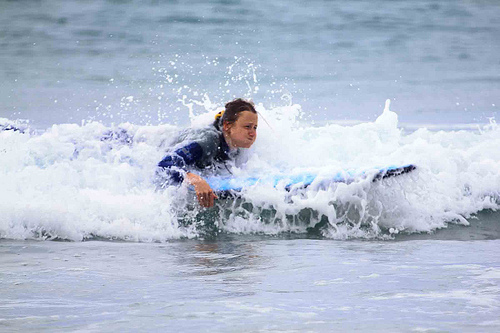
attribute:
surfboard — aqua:
[183, 162, 414, 199]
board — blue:
[161, 157, 424, 201]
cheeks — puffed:
[228, 122, 256, 147]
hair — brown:
[213, 98, 257, 125]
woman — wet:
[87, 88, 258, 218]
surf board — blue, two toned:
[188, 162, 418, 200]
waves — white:
[13, 112, 498, 215]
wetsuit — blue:
[98, 126, 230, 184]